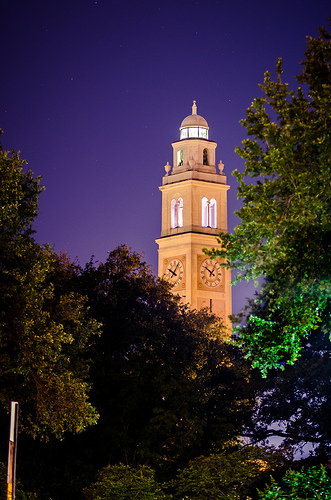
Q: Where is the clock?
A: In the tower.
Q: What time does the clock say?
A: 10:05.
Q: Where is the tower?
A: It is outside.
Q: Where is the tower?
A: Behind the trees.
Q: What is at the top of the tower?
A: A light.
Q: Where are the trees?
A: In front of the tower.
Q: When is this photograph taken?
A: In the evening.